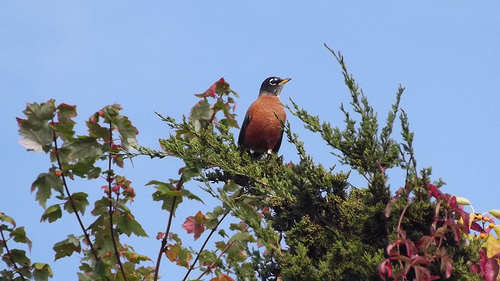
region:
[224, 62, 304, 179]
a bird is sitting in a tree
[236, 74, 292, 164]
the bird is a red robin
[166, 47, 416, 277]
the robin is sitting in an evergreen tree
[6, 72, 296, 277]
a maple tree is behind the robin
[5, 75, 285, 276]
the maple tree leaves are beginning to turn red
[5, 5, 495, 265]
the sky is clear and blue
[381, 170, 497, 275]
sumac is turning to fall colors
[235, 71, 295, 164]
the bird has a red breast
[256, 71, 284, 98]
the robin's head is black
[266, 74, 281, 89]
the robin has white markings around the eye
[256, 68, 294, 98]
the head of a bird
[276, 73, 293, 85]
the beak of a bird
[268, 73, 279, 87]
the eye of a bird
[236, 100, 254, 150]
the wing of a bird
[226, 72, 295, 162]
a bird on the tree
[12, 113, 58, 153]
a green leaf on the tree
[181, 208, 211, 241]
a brown leaf on the tree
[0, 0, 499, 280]
a clear blue sky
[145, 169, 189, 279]
a branch of the tree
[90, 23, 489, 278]
the top of a tree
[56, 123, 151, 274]
broad green leaves against blue sky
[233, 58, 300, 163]
bird with brown breast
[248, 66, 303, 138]
bird with yellow tip beak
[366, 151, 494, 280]
reddish leaves against blue sky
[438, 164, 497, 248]
pink and yellow leaves against blue sky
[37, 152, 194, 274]
thin brown branches against blue sky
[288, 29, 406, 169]
pointy evergreen leaves against blue sky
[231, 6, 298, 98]
black bird head against cloudless sky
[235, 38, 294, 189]
bird sitting in tree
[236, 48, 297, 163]
bird with black wings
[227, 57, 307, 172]
a red breasted bird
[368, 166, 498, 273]
purple foliage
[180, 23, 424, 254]
a wild bird in a tree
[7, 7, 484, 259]
spring foliage from several trees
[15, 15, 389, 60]
a blue sky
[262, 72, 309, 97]
a bird looking far away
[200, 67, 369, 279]
a bird in a juniper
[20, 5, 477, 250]
a nature scene on a sunny day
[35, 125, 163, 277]
thin branches from a leafy tree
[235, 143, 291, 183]
a bird's feet grasping a branch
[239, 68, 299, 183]
robin red-breast perched in a tree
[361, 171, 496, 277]
pink trumpet flowers with yellow middles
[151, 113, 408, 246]
a pine tree branch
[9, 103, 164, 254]
a deciduous tree with red and green leaves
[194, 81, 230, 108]
a red oak leaf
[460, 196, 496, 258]
yellow flower bud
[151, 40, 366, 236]
bird perched on a pine branch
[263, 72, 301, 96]
robin head with a glossy eye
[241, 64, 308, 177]
bird with a yellow beak on a tree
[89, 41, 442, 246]
bird above the trees and flowers